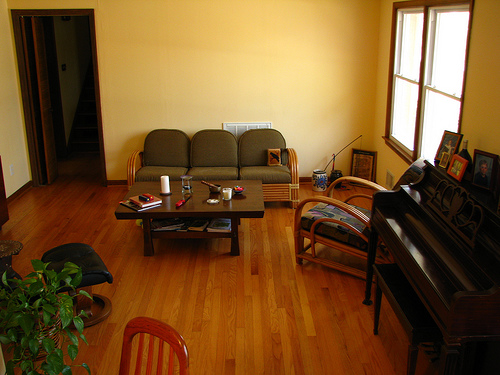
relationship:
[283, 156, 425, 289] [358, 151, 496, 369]
chair next to piano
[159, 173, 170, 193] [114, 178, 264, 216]
candle on table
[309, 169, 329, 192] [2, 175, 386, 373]
vase on floor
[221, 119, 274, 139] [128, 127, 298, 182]
vent behind sofa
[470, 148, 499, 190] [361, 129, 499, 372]
picture on top of piano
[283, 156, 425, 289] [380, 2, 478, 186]
chair sitting by window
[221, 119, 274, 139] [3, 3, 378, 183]
vent on wall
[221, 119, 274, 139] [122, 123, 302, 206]
vent behind sofa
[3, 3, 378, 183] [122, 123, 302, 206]
wall behind sofa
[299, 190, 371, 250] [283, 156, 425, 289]
cushion in chair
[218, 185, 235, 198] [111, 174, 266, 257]
cup sitting on table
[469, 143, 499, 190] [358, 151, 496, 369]
picture on piano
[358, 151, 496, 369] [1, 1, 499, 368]
piano in room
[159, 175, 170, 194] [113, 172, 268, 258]
candle on coffee table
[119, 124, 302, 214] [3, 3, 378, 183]
couch against wall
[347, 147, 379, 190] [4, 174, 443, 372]
picture on floor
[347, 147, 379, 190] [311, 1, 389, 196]
picture in corner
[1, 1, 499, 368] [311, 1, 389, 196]
room has corner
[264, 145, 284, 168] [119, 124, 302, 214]
pillow on couch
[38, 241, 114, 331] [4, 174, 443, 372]
foot stool on floor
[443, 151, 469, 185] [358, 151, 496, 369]
picture on piano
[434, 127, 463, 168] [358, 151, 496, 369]
picture on piano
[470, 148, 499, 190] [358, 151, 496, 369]
picture on piano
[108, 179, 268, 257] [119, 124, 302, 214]
coffee table in front of couch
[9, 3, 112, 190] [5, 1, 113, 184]
door has door frame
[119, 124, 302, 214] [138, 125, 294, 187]
couch has cushions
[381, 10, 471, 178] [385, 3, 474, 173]
window has frame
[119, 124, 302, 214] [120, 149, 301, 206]
couch has trim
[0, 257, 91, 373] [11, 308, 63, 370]
vine plant in basket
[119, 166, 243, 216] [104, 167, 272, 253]
objects on coffee table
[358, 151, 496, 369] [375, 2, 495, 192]
piano against wall